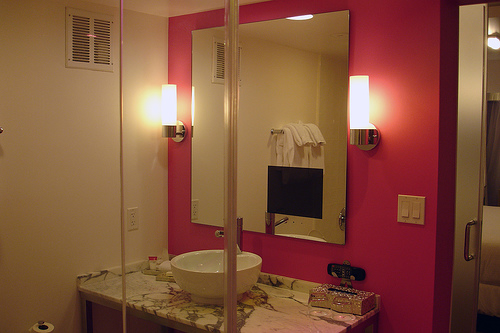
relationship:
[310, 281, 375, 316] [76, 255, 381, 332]
kleenex on counter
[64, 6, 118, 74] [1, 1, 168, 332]
vent on wall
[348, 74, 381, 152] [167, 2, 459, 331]
light on wall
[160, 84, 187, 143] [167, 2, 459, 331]
light on wall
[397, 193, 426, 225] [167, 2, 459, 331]
light switch on wall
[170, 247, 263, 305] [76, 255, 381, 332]
sink on counter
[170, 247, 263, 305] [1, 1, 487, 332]
sink in bathroom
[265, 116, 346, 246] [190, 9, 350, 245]
reflection in mirror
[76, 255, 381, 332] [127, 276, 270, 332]
counter has graphics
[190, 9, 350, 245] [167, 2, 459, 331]
mirror mounted on wall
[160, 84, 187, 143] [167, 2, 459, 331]
light mounted on wall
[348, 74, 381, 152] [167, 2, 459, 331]
light mounted on wall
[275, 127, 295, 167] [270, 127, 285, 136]
towel hanging on bar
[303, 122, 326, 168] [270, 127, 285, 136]
towel hanging on bar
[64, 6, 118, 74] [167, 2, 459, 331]
vent on wall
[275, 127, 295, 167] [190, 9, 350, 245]
towel in mirror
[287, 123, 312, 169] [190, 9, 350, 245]
towel in mirror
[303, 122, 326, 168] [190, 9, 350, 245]
towel in mirror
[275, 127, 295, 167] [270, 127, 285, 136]
towel on bar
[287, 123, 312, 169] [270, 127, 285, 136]
towel on bar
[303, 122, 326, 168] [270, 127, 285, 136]
towel on bar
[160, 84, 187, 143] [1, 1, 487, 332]
light in bathroom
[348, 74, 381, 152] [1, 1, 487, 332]
light in bathroom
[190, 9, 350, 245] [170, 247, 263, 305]
mirror over sink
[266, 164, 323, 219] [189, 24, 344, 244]
something black in mirror